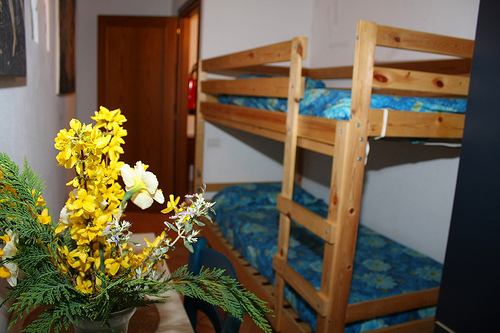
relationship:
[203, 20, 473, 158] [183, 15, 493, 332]
bed on beds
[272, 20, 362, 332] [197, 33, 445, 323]
ladder on beds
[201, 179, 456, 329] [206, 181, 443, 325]
bed with bed spread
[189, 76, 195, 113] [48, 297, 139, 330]
extinguisher in flowerpot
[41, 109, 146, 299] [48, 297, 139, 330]
flower in flowerpot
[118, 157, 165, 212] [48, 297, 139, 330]
rose in a flowerpot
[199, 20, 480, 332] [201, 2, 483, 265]
bunkbeds against wall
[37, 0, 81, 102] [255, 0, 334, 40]
picture hanging on wall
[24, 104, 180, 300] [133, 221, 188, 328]
flower on table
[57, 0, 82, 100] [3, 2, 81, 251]
picture hanging on wall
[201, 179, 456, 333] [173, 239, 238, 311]
bed in ground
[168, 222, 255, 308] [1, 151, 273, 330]
leaves on evergreens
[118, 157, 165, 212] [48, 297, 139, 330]
rose in flowerpot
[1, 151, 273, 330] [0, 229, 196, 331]
evergreens mixed in flowerpot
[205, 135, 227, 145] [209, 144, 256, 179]
light switch on wall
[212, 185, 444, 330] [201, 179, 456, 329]
bedspread on bed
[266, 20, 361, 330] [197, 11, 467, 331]
ladder on bunk bed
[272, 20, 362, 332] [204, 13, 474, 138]
ladder climb top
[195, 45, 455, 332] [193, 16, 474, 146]
bed on top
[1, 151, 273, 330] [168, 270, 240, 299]
evergreens has leaves